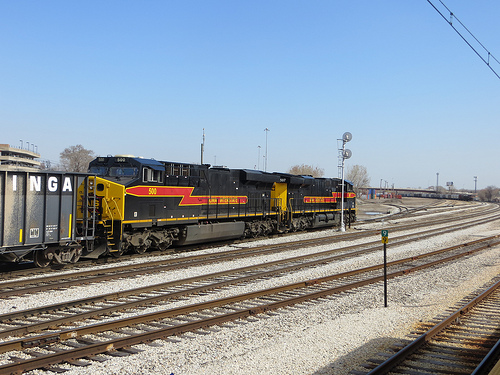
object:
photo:
[0, 0, 500, 375]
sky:
[1, 1, 500, 191]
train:
[1, 154, 357, 270]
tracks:
[0, 235, 500, 375]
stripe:
[126, 185, 249, 206]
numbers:
[149, 187, 158, 194]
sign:
[381, 229, 389, 243]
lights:
[117, 158, 125, 163]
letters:
[12, 174, 72, 192]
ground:
[0, 195, 500, 375]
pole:
[383, 244, 388, 307]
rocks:
[365, 285, 413, 314]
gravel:
[318, 300, 369, 332]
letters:
[208, 198, 237, 203]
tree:
[345, 163, 372, 198]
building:
[0, 143, 42, 172]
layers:
[358, 187, 479, 201]